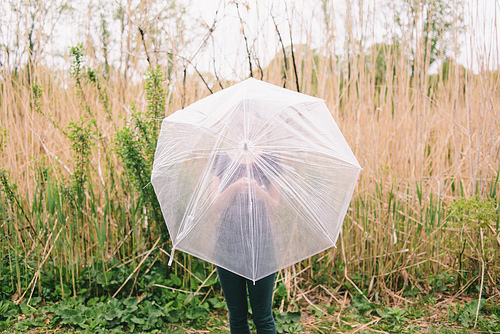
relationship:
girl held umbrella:
[202, 106, 286, 334] [150, 75, 358, 294]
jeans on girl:
[217, 235, 279, 333] [202, 106, 286, 334]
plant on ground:
[0, 291, 179, 332] [11, 256, 478, 316]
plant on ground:
[0, 291, 179, 332] [19, 296, 476, 321]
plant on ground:
[23, 66, 477, 254] [9, 280, 454, 331]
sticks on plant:
[19, 230, 59, 283] [23, 66, 477, 254]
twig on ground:
[303, 271, 430, 311] [15, 293, 484, 321]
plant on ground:
[0, 291, 179, 332] [17, 287, 477, 331]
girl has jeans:
[202, 106, 286, 334] [217, 235, 279, 333]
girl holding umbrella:
[202, 106, 286, 334] [149, 69, 378, 283]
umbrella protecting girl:
[149, 69, 378, 283] [202, 106, 286, 334]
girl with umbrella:
[202, 106, 286, 334] [142, 77, 369, 288]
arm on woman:
[215, 184, 280, 223] [205, 79, 316, 300]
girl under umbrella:
[202, 106, 286, 334] [150, 75, 358, 294]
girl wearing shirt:
[180, 68, 304, 314] [206, 145, 295, 238]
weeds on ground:
[369, 278, 442, 326] [193, 315, 222, 328]